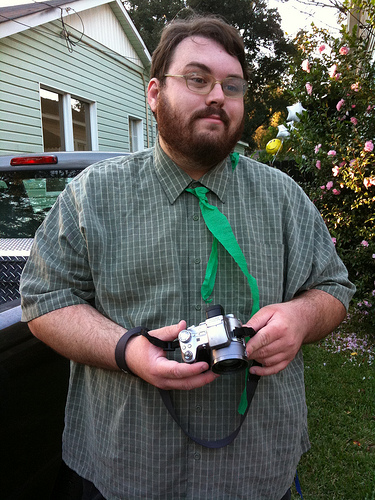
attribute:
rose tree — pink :
[259, 40, 362, 196]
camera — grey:
[173, 301, 264, 378]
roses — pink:
[299, 69, 345, 142]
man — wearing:
[106, 78, 301, 267]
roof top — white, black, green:
[1, 0, 163, 68]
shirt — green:
[19, 133, 355, 498]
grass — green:
[316, 370, 367, 487]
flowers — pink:
[299, 35, 374, 204]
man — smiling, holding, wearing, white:
[18, 20, 356, 497]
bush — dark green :
[303, 118, 343, 136]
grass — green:
[295, 308, 372, 498]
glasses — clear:
[160, 64, 250, 99]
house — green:
[3, 2, 254, 217]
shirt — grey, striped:
[36, 144, 345, 465]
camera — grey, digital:
[150, 278, 293, 376]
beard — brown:
[136, 85, 276, 178]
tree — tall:
[153, 2, 286, 162]